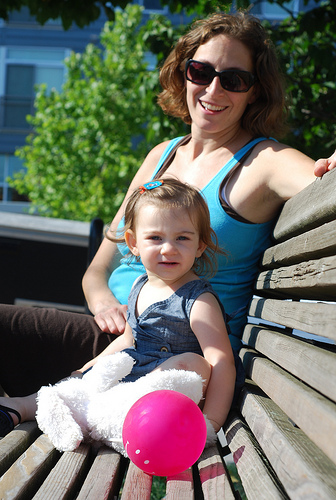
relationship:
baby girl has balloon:
[0, 176, 236, 448] [120, 386, 211, 478]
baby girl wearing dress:
[0, 176, 236, 448] [81, 273, 227, 383]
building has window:
[2, 0, 335, 215] [3, 54, 50, 143]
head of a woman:
[155, 12, 287, 137] [1, 10, 320, 369]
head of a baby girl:
[125, 182, 208, 279] [0, 176, 237, 431]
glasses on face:
[184, 57, 256, 93] [185, 32, 253, 134]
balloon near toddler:
[106, 379, 208, 492] [130, 145, 237, 385]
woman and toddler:
[0, 9, 335, 398] [1, 170, 331, 498]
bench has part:
[3, 163, 333, 498] [2, 414, 326, 497]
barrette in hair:
[138, 179, 164, 192] [140, 14, 317, 143]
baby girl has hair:
[0, 176, 236, 448] [140, 14, 317, 143]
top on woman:
[123, 122, 263, 342] [0, 9, 335, 398]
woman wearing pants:
[0, 9, 335, 398] [0, 303, 121, 396]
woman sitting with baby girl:
[0, 9, 335, 398] [0, 176, 236, 448]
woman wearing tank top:
[204, 224, 269, 274] [108, 134, 277, 354]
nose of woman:
[206, 76, 223, 99] [0, 9, 335, 398]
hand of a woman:
[88, 299, 137, 334] [77, 12, 334, 335]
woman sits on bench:
[0, 9, 335, 398] [3, 163, 333, 498]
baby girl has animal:
[0, 176, 236, 448] [33, 351, 216, 461]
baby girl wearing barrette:
[0, 176, 236, 448] [138, 179, 164, 192]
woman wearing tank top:
[0, 9, 335, 398] [103, 132, 259, 332]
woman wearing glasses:
[0, 9, 335, 398] [184, 56, 256, 95]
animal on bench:
[36, 352, 208, 451] [3, 163, 333, 498]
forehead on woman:
[198, 16, 262, 64] [91, 8, 317, 244]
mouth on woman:
[198, 98, 228, 115] [36, 2, 313, 424]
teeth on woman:
[190, 94, 232, 114] [101, 32, 307, 303]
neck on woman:
[189, 119, 241, 144] [0, 9, 335, 398]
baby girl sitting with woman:
[0, 176, 236, 448] [20, 6, 334, 431]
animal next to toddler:
[33, 351, 216, 461] [0, 175, 247, 439]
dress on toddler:
[83, 271, 246, 403] [0, 175, 247, 439]